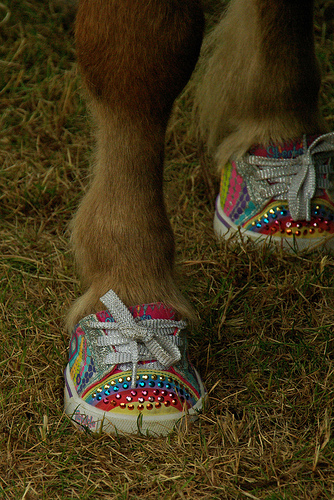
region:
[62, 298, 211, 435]
multi-colored shoes with laces for ungulates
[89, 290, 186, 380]
silver shoelaces fastened to ungulate feet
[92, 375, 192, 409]
fake gemstones of assorted colors on toe of shoe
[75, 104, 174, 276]
front proper-left calf of ungulate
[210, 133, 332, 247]
a second shoe on the ungulate's left front foot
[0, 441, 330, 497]
trampled and barely watered grass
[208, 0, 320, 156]
leg with slightly thicker and longer fur than the other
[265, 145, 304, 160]
the word "Sketchers" in blue text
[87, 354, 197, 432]
rainbow on the show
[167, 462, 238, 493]
the grass is short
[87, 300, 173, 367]
laces on the shoe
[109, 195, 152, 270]
fur on the leg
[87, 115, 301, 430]
shoes on the horse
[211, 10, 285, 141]
fur on the leg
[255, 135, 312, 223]
shoelace on the shoe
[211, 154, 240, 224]
side of the shoe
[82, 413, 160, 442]
bottom of the shoe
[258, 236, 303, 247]
side of the shoe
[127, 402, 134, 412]
the rhinestone is orange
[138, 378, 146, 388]
the rhinestone is blue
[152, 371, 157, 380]
the rhinestone is yellow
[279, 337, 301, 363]
the grass is green in color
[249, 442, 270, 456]
the grass is dead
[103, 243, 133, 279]
the leg is furry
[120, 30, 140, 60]
the fur is brown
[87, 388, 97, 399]
The circle is yellow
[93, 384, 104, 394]
The circle is yellow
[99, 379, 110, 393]
The circle is yellow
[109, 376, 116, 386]
The circle is yellow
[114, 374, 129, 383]
The circle is yellow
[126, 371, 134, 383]
The circle is yellow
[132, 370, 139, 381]
The circle is yellow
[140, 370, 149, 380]
The circle is yellow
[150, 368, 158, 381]
The circle is yellow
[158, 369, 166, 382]
The circle is yellow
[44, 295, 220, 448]
shoe on the animal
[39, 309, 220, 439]
shoe on the animal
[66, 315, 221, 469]
shoe on the animal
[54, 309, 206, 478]
shoe on the animal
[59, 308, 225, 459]
shoe on the animal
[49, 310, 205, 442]
shoe on the animal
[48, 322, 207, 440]
shoe on the animal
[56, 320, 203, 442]
shoe on the animal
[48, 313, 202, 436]
shoe on the animal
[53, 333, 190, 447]
shoe on the animal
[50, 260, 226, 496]
a shoe on the dog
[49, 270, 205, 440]
a shoe on the dog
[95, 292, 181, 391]
laces on the shoe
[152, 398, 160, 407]
rhinestone on the shoe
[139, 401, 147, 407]
rhinestone on the shoe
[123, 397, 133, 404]
rhinestone on the shoe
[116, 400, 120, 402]
rhinestone on the shoe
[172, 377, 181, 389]
rhinestone on the shoe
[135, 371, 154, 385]
rhinestone on the shoe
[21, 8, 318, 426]
animal in the background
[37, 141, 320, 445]
shoes in the background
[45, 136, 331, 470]
animal wearing shoe in the bakground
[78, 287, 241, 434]
white shoe laces in the background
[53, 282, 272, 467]
rhinestones on the shoe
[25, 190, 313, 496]
brown grass on the ground